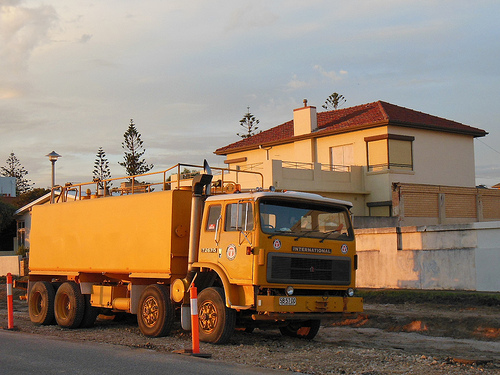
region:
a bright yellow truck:
[7, 166, 364, 343]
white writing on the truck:
[200, 246, 225, 261]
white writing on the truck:
[291, 247, 331, 257]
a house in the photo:
[206, 100, 498, 292]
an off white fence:
[353, 226, 498, 291]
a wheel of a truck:
[55, 283, 83, 328]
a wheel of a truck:
[189, 289, 232, 344]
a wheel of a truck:
[130, 288, 172, 340]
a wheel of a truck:
[25, 278, 55, 327]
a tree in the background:
[116, 118, 163, 183]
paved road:
[1, 331, 261, 370]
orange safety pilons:
[5, 272, 211, 357]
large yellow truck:
[24, 161, 363, 343]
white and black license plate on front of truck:
[278, 297, 297, 305]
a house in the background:
[158, 99, 488, 223]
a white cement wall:
[343, 222, 497, 288]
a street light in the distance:
[45, 149, 60, 202]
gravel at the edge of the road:
[1, 312, 499, 372]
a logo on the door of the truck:
[225, 242, 237, 258]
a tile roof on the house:
[212, 99, 487, 153]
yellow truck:
[30, 155, 362, 355]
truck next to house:
[14, 57, 484, 343]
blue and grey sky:
[1, 0, 498, 100]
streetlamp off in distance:
[44, 146, 64, 193]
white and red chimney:
[290, 93, 320, 158]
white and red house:
[210, 93, 497, 242]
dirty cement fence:
[355, 224, 498, 289]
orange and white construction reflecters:
[187, 283, 202, 350]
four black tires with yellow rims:
[21, 275, 236, 340]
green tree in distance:
[115, 116, 157, 181]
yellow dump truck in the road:
[9, 152, 373, 352]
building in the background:
[219, 72, 494, 181]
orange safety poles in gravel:
[3, 266, 20, 343]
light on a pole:
[39, 137, 68, 200]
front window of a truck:
[251, 193, 358, 242]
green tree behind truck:
[114, 116, 156, 189]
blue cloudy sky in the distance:
[347, 57, 495, 106]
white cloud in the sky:
[4, 5, 59, 105]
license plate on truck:
[274, 292, 301, 311]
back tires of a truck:
[22, 277, 92, 330]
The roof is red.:
[205, 86, 490, 151]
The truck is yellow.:
[2, 147, 388, 337]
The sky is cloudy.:
[0, 5, 492, 187]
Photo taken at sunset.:
[27, 15, 486, 362]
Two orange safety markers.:
[0, 261, 221, 348]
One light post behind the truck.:
[40, 135, 70, 214]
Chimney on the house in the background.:
[276, 82, 325, 176]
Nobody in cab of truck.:
[198, 190, 373, 335]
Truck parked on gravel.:
[4, 285, 447, 367]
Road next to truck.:
[2, 322, 287, 372]